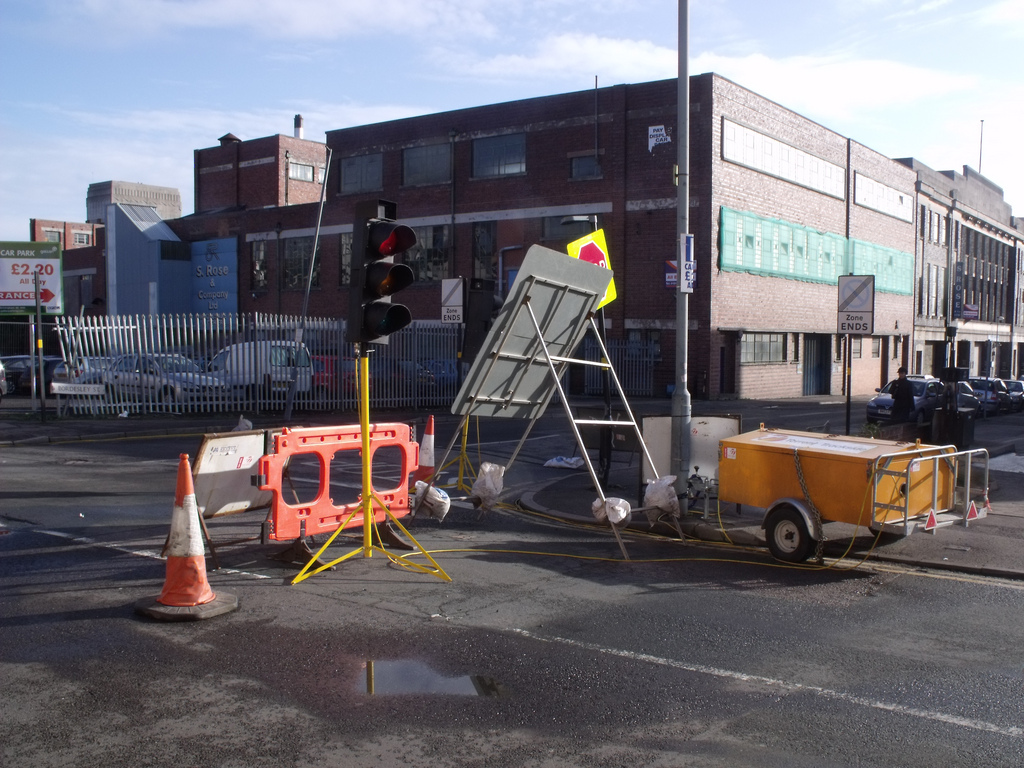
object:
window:
[288, 161, 315, 183]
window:
[317, 166, 328, 184]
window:
[339, 149, 382, 194]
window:
[400, 148, 454, 187]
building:
[0, 63, 1020, 397]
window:
[469, 130, 524, 179]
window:
[470, 220, 500, 292]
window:
[542, 215, 594, 238]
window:
[738, 328, 786, 366]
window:
[871, 336, 881, 359]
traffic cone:
[153, 449, 218, 612]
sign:
[559, 225, 616, 308]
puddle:
[349, 645, 487, 702]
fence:
[49, 311, 459, 412]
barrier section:
[258, 415, 424, 543]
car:
[861, 370, 956, 428]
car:
[944, 379, 983, 417]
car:
[962, 375, 1009, 412]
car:
[1008, 380, 1024, 412]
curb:
[849, 388, 872, 405]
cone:
[137, 450, 237, 628]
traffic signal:
[344, 191, 417, 363]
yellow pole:
[284, 344, 454, 592]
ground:
[203, 557, 1024, 697]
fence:
[43, 313, 355, 421]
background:
[2, 13, 472, 425]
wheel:
[759, 497, 820, 567]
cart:
[703, 417, 993, 570]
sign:
[0, 258, 63, 315]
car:
[100, 350, 233, 409]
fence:
[49, 311, 142, 420]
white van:
[205, 338, 315, 398]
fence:
[47, 314, 257, 412]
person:
[885, 365, 916, 435]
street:
[746, 382, 922, 433]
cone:
[416, 408, 448, 483]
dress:
[885, 378, 921, 421]